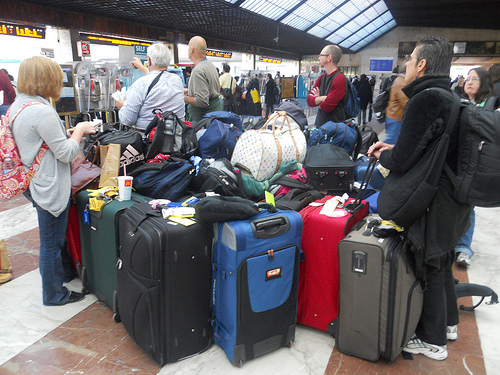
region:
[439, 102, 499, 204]
a big black backpack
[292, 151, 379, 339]
a tall red suitcase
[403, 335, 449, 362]
the shoe of a man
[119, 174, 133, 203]
a paper cup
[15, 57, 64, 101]
the head of a blonde woman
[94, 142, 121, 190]
a brown paper bag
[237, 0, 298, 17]
part of a window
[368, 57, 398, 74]
a blue and white sign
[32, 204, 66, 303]
the leg of a woman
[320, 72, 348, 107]
the arm of a man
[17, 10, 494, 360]
group of people waiting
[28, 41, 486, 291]
group of people waiting with luggage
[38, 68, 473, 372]
group of people with luggage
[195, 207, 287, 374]
blue piece of luggage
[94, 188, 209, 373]
black piece of luggage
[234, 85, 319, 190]
white and black purse on luggage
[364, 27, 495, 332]
man standing with backpack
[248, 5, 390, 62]
electronic signs at station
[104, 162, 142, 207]
cup of soda on top of luggage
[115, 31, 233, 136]
two men standing and waiting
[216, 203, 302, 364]
black and blue suitcase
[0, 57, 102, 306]
a woman wearing a backpack next to luggage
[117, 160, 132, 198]
mcdonalds cup with straw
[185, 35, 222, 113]
top half of an older man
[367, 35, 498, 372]
a woman standing next to luggage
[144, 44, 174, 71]
the back of a man's head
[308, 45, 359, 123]
man standing with red and black shirt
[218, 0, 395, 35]
windows along the roof of a building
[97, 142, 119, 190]
brown paper bag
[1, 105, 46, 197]
a woman's backpack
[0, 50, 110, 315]
Woman with backpack standing at airport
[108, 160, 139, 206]
Drinking cup with straw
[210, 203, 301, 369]
Blue, black and gray suitcase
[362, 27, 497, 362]
Man with backpack waiting at airport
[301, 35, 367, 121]
Man with red and black shirt with backpack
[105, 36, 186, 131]
Man pointing with his finger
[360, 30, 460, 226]
Man with black bag over shoulder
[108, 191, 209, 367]
Black suitcase with identification tags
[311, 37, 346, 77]
Man wearing eyeglasses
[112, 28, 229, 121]
Two men at airport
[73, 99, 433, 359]
a large pile of suitcases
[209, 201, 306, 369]
a blue suitcase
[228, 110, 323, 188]
a white bag of luggage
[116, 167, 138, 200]
a paper mc donalds cup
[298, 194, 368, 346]
a large red suitcase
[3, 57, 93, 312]
a woman standing with a backpack on her back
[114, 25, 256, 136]
two men talking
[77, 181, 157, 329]
a large green suitcase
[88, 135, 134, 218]
a mc donalds bag and drink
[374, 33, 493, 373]
a man in all black standing with his luggage